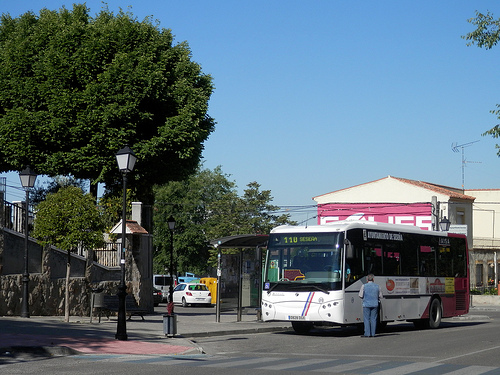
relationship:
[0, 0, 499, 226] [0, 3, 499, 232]
cloud in sky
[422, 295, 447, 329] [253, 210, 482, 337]
tire on bus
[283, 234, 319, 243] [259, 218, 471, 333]
read out on bus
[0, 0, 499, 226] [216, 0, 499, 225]
cloud in blue sky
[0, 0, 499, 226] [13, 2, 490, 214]
cloud in sky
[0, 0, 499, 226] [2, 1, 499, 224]
cloud in blue sky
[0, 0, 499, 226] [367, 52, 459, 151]
cloud in sky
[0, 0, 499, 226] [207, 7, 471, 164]
cloud in sky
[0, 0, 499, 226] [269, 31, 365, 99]
cloud in sky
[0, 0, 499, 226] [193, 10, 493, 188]
cloud in sky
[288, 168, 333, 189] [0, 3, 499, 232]
cloud in sky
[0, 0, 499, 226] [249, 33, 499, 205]
cloud in sky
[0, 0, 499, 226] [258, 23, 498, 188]
cloud in sky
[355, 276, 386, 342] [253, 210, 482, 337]
person by bus